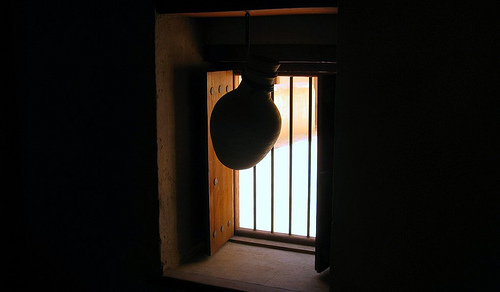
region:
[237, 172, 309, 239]
the bars are brown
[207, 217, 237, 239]
the screws are brown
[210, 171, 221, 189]
the screw is round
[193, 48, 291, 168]
the light is off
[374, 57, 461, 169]
the wall is dark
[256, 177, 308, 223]
white is outside the window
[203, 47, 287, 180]
the light is hanging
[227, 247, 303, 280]
the window seal is wooden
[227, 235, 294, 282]
the window seal is brown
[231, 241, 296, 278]
the window seal is smooth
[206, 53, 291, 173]
clay vase handing in air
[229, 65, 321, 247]
window is square with bars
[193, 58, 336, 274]
wooden and metal window shutters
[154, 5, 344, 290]
window sill is brown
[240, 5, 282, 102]
rope is hanging the vase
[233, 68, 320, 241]
bars are skinny and run vertical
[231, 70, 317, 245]
bright sunlight is shining through bars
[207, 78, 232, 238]
metal circles on window shutter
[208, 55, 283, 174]
pot is light brown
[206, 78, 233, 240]
metal on shutter is black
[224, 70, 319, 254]
this is a window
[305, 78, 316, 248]
a grill on a window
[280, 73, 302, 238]
a grill on a window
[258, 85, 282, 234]
a grill on a window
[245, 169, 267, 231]
a grill on a window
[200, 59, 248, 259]
this is a window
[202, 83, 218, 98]
a nail on the window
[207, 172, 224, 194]
a nail on the window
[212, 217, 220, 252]
a nail on the window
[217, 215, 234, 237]
a nail on the window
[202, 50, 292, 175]
A vase hanging in the window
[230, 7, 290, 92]
The rope hanging the vase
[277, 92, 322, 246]
The bars are made of metal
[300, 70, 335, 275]
Te door is made of wood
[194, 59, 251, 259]
The color of the door is brown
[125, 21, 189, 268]
The corner of the wall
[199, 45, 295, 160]
The vase is the color white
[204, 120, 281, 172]
The bottom of the vase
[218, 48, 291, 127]
The top of the vase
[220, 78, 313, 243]
The sun coming through the door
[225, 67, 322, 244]
bars on outer window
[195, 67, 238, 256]
brown wooden window shutter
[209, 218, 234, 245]
silver rivets in window shutter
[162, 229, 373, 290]
wooden window ledge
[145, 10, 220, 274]
wall left side of window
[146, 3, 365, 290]
small window alcove front of window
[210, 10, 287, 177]
vase-like object hanging in window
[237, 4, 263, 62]
chain attached to hanging object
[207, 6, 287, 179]
object secured to wall with chain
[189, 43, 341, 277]
small outer wall window